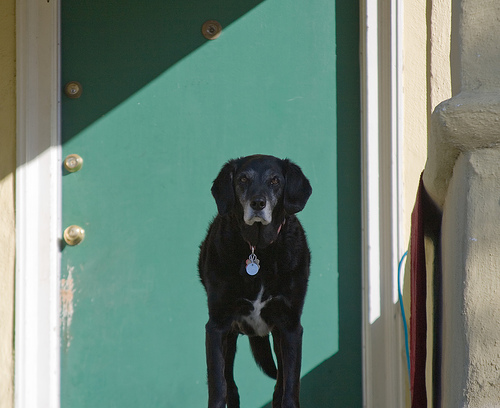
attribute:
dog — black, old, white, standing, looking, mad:
[198, 152, 315, 407]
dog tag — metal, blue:
[246, 247, 260, 278]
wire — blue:
[395, 245, 414, 407]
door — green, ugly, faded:
[61, 0, 362, 406]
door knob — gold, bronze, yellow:
[61, 224, 87, 248]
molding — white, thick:
[16, 0, 58, 407]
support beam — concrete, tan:
[421, 0, 498, 405]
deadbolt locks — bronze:
[61, 81, 84, 177]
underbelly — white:
[239, 300, 272, 340]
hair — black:
[196, 153, 314, 400]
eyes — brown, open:
[236, 173, 284, 190]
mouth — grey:
[241, 205, 276, 225]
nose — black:
[252, 196, 267, 213]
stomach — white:
[236, 314, 276, 343]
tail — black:
[250, 333, 281, 380]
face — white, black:
[229, 158, 286, 230]